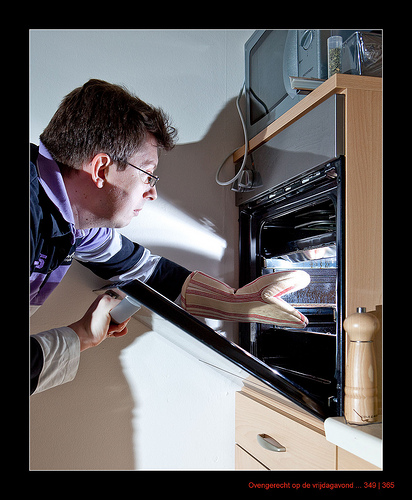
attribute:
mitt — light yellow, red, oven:
[185, 252, 325, 342]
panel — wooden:
[339, 72, 386, 431]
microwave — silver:
[206, 105, 368, 343]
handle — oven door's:
[105, 294, 146, 328]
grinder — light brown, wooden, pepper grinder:
[345, 305, 372, 413]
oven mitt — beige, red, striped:
[146, 239, 363, 389]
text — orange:
[248, 482, 393, 487]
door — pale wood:
[230, 384, 343, 471]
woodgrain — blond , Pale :
[268, 421, 314, 441]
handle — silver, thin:
[255, 427, 291, 454]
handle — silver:
[254, 430, 286, 455]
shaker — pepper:
[329, 308, 410, 438]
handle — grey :
[114, 298, 139, 322]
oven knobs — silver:
[231, 170, 251, 193]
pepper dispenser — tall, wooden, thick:
[342, 297, 378, 425]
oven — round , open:
[91, 93, 344, 422]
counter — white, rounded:
[308, 408, 396, 472]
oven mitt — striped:
[179, 264, 314, 332]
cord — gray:
[215, 79, 247, 186]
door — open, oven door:
[89, 277, 324, 423]